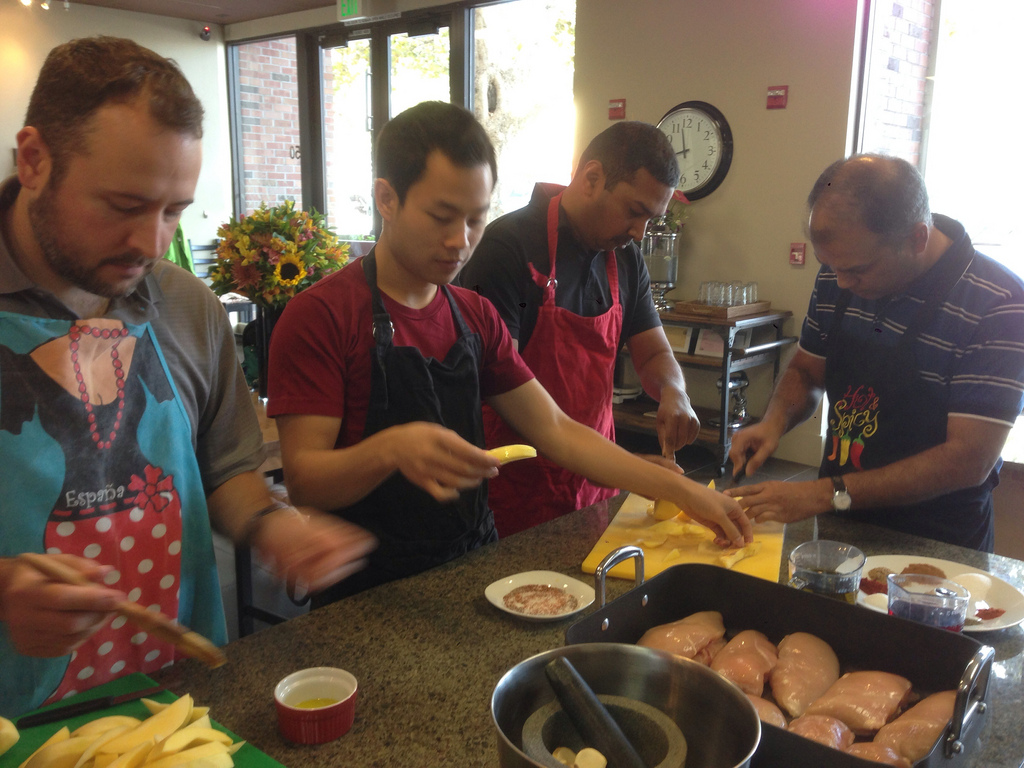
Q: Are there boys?
A: No, there are no boys.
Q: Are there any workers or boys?
A: No, there are no boys or workers.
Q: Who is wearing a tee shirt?
A: The man is wearing a tee shirt.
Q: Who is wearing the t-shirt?
A: The man is wearing a tee shirt.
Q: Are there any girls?
A: No, there are no girls.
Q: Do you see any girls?
A: No, there are no girls.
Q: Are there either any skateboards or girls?
A: No, there are no girls or skateboards.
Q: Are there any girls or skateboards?
A: No, there are no girls or skateboards.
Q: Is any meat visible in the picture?
A: Yes, there is meat.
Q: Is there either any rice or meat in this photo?
A: Yes, there is meat.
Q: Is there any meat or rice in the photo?
A: Yes, there is meat.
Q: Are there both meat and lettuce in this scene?
A: No, there is meat but no lettuce.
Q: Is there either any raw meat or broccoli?
A: Yes, there is raw meat.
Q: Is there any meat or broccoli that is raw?
A: Yes, the meat is raw.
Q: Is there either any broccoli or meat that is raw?
A: Yes, the meat is raw.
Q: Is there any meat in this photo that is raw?
A: Yes, there is raw meat.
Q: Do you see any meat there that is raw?
A: Yes, there is meat that is raw.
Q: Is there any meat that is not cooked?
A: Yes, there is raw meat.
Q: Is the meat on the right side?
A: Yes, the meat is on the right of the image.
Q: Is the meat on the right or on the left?
A: The meat is on the right of the image.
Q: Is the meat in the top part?
A: No, the meat is in the bottom of the image.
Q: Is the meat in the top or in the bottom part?
A: The meat is in the bottom of the image.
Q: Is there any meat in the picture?
A: Yes, there is meat.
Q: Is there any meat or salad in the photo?
A: Yes, there is meat.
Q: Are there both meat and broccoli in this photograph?
A: No, there is meat but no broccoli.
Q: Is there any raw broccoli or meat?
A: Yes, there is raw meat.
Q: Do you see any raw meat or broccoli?
A: Yes, there is raw meat.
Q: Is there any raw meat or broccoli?
A: Yes, there is raw meat.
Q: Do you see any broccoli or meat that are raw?
A: Yes, the meat is raw.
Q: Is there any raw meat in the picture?
A: Yes, there is raw meat.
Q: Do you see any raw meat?
A: Yes, there is raw meat.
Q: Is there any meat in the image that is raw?
A: Yes, there is meat that is raw.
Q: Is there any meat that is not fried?
A: Yes, there is raw meat.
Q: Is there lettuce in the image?
A: No, there is no lettuce.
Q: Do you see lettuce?
A: No, there is no lettuce.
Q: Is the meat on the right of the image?
A: Yes, the meat is on the right of the image.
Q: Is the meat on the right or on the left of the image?
A: The meat is on the right of the image.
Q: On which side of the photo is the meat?
A: The meat is on the right of the image.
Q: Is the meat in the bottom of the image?
A: Yes, the meat is in the bottom of the image.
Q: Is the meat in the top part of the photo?
A: No, the meat is in the bottom of the image.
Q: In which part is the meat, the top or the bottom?
A: The meat is in the bottom of the image.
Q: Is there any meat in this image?
A: Yes, there is meat.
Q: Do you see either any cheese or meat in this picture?
A: Yes, there is meat.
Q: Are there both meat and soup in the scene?
A: No, there is meat but no soup.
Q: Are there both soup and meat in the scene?
A: No, there is meat but no soup.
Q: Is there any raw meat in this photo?
A: Yes, there is raw meat.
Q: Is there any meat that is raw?
A: Yes, there is raw meat.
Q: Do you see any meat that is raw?
A: Yes, there is meat that is raw.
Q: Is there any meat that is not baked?
A: Yes, there is raw meat.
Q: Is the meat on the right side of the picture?
A: Yes, the meat is on the right of the image.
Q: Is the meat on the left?
A: No, the meat is on the right of the image.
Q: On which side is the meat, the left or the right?
A: The meat is on the right of the image.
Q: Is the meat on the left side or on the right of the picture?
A: The meat is on the right of the image.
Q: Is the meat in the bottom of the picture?
A: Yes, the meat is in the bottom of the image.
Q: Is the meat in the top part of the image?
A: No, the meat is in the bottom of the image.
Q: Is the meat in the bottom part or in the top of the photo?
A: The meat is in the bottom of the image.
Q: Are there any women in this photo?
A: No, there are no women.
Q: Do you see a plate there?
A: Yes, there is a plate.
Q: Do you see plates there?
A: Yes, there is a plate.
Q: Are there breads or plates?
A: Yes, there is a plate.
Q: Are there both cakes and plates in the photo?
A: No, there is a plate but no cakes.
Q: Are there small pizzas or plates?
A: Yes, there is a small plate.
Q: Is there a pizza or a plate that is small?
A: Yes, the plate is small.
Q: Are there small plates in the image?
A: Yes, there is a small plate.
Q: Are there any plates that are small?
A: Yes, there is a plate that is small.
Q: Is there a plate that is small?
A: Yes, there is a plate that is small.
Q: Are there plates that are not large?
A: Yes, there is a small plate.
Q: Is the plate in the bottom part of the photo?
A: Yes, the plate is in the bottom of the image.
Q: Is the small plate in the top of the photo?
A: No, the plate is in the bottom of the image.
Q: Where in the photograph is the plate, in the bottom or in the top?
A: The plate is in the bottom of the image.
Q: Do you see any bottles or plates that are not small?
A: No, there is a plate but it is small.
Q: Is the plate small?
A: Yes, the plate is small.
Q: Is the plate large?
A: No, the plate is small.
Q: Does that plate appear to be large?
A: No, the plate is small.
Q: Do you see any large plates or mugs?
A: No, there is a plate but it is small.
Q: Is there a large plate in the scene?
A: No, there is a plate but it is small.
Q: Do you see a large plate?
A: No, there is a plate but it is small.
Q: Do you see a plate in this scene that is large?
A: No, there is a plate but it is small.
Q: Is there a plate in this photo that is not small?
A: No, there is a plate but it is small.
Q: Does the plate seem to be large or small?
A: The plate is small.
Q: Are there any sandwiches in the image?
A: No, there are no sandwiches.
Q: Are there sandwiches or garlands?
A: No, there are no sandwiches or garlands.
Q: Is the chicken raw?
A: Yes, the chicken is raw.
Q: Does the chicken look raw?
A: Yes, the chicken is raw.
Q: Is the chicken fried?
A: No, the chicken is raw.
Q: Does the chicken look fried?
A: No, the chicken is raw.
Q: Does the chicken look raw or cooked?
A: The chicken is raw.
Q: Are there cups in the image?
A: Yes, there is a cup.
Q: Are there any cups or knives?
A: Yes, there is a cup.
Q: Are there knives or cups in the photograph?
A: Yes, there is a cup.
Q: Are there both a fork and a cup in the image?
A: No, there is a cup but no forks.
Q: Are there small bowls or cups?
A: Yes, there is a small cup.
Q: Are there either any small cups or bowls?
A: Yes, there is a small cup.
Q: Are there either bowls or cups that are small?
A: Yes, the cup is small.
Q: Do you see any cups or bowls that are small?
A: Yes, the cup is small.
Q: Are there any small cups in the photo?
A: Yes, there is a small cup.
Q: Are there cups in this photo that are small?
A: Yes, there is a cup that is small.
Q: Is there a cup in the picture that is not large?
A: Yes, there is a small cup.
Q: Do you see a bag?
A: No, there are no bags.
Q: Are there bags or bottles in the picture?
A: No, there are no bags or bottles.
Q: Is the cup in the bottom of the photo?
A: Yes, the cup is in the bottom of the image.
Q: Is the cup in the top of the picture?
A: No, the cup is in the bottom of the image.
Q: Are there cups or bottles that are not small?
A: No, there is a cup but it is small.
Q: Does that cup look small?
A: Yes, the cup is small.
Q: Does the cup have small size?
A: Yes, the cup is small.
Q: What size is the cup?
A: The cup is small.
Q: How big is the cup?
A: The cup is small.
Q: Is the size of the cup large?
A: No, the cup is small.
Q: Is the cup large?
A: No, the cup is small.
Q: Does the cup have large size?
A: No, the cup is small.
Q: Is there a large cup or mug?
A: No, there is a cup but it is small.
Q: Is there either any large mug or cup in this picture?
A: No, there is a cup but it is small.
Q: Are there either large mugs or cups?
A: No, there is a cup but it is small.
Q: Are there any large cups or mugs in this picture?
A: No, there is a cup but it is small.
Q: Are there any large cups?
A: No, there is a cup but it is small.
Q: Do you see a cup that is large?
A: No, there is a cup but it is small.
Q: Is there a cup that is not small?
A: No, there is a cup but it is small.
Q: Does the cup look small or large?
A: The cup is small.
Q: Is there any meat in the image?
A: Yes, there is meat.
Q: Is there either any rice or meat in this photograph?
A: Yes, there is meat.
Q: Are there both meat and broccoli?
A: No, there is meat but no broccoli.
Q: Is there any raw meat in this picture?
A: Yes, there is raw meat.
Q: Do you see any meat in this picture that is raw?
A: Yes, there is meat that is raw.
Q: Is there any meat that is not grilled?
A: Yes, there is raw meat.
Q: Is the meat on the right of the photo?
A: Yes, the meat is on the right of the image.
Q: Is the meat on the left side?
A: No, the meat is on the right of the image.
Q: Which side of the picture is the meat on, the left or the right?
A: The meat is on the right of the image.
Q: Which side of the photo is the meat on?
A: The meat is on the right of the image.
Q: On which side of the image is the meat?
A: The meat is on the right of the image.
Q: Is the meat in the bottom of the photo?
A: Yes, the meat is in the bottom of the image.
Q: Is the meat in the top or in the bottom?
A: The meat is in the bottom of the image.